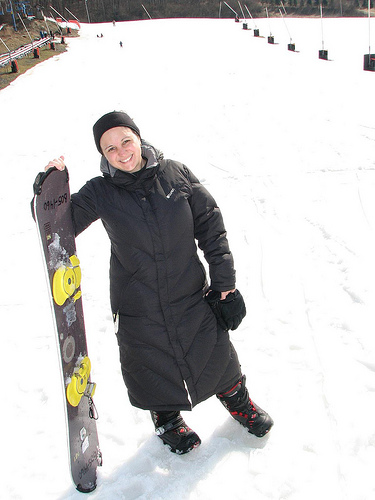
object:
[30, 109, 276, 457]
person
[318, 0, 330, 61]
poles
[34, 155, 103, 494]
snowboard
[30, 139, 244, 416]
coat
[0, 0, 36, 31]
tree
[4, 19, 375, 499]
snow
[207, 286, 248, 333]
glove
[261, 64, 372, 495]
ground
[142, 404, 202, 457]
boot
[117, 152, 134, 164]
smile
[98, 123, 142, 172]
woman's face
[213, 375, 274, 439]
boot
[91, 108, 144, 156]
hat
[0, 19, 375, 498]
ground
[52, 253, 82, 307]
foothold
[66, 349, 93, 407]
foothold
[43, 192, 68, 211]
number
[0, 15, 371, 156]
snow course